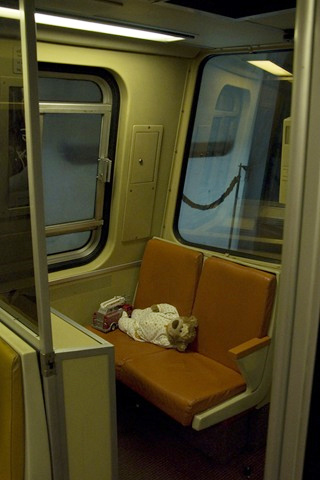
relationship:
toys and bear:
[90, 294, 132, 337] [121, 301, 200, 356]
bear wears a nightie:
[121, 301, 200, 356] [119, 304, 179, 347]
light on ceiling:
[1, 8, 187, 43] [1, 2, 296, 61]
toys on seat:
[95, 294, 202, 353] [81, 233, 273, 426]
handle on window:
[98, 154, 112, 184] [9, 69, 114, 273]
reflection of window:
[207, 75, 256, 161] [9, 69, 114, 273]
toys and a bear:
[90, 294, 132, 337] [121, 301, 200, 356]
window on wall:
[9, 69, 114, 273] [4, 38, 196, 329]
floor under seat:
[121, 388, 267, 479] [81, 233, 273, 426]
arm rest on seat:
[227, 335, 279, 389] [81, 233, 273, 426]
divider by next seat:
[2, 0, 51, 354] [1, 318, 56, 479]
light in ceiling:
[1, 8, 187, 43] [1, 2, 296, 61]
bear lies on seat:
[121, 301, 200, 356] [81, 233, 273, 426]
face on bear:
[172, 317, 190, 343] [121, 301, 200, 356]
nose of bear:
[172, 319, 181, 334] [121, 301, 200, 356]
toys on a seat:
[90, 294, 132, 337] [81, 233, 273, 426]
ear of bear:
[186, 313, 202, 331] [121, 301, 200, 356]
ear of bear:
[173, 344, 190, 355] [121, 301, 200, 356]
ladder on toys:
[102, 293, 127, 313] [90, 294, 132, 337]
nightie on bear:
[119, 304, 179, 347] [121, 301, 200, 356]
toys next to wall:
[90, 294, 132, 337] [4, 38, 196, 329]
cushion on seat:
[90, 320, 247, 424] [81, 233, 273, 426]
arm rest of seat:
[227, 335, 279, 389] [81, 233, 273, 426]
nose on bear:
[172, 319, 181, 334] [121, 301, 200, 356]